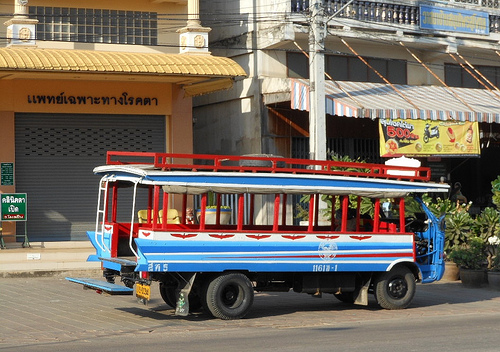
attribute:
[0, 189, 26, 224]
sign — green, white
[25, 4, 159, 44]
window — large, multipane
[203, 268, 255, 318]
tire — black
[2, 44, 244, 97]
awning — yellow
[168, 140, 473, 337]
truck — red, blue, coated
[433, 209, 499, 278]
plant — green, potted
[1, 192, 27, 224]
sign — small, green, white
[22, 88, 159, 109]
lettering — black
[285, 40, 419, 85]
window — long, multipane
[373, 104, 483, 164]
banner — hanging, yellow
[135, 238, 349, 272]
letters — white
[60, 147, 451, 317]
bus — red, blue, white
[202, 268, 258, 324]
wheel — black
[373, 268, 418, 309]
wheel — black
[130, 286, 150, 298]
number — yellow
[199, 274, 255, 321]
wheel — black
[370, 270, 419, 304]
wheel — black